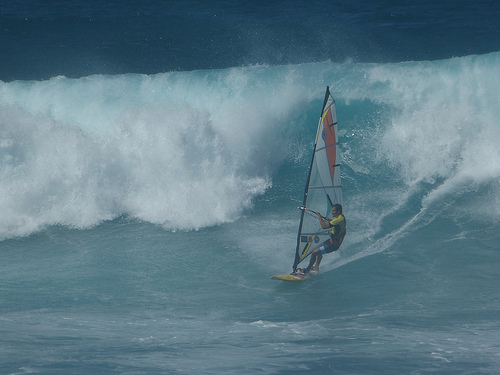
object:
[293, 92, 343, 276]
mast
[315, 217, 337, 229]
arm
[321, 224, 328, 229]
elbow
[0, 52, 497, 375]
water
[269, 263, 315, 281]
surfboard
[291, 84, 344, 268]
sail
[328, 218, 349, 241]
shirt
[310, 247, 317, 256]
knees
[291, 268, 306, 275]
feet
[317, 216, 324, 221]
hands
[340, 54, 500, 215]
wave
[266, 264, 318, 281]
board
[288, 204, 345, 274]
man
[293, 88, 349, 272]
pole